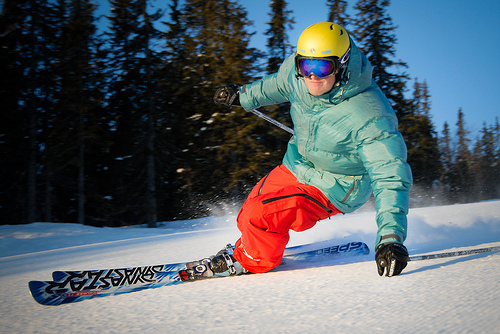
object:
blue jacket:
[238, 35, 414, 244]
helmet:
[295, 22, 351, 58]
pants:
[231, 163, 341, 272]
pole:
[409, 248, 497, 260]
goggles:
[295, 55, 340, 77]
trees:
[1, 0, 498, 227]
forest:
[1, 1, 500, 221]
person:
[204, 21, 416, 281]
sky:
[0, 0, 498, 136]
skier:
[204, 12, 428, 282]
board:
[29, 238, 389, 305]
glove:
[376, 242, 409, 275]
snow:
[0, 197, 497, 332]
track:
[247, 204, 273, 224]